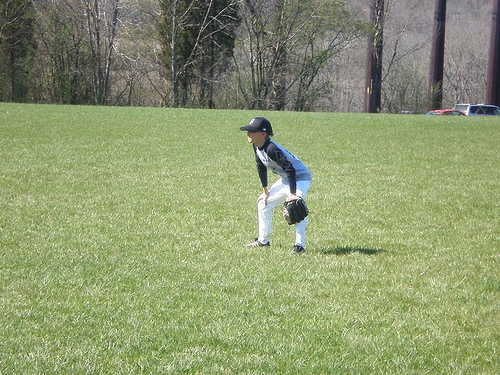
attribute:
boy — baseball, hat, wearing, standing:
[211, 118, 316, 249]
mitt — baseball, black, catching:
[278, 203, 313, 234]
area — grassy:
[143, 173, 217, 231]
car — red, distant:
[430, 112, 456, 123]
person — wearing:
[232, 93, 329, 212]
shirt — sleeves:
[248, 151, 303, 194]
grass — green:
[135, 167, 202, 273]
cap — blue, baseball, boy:
[242, 120, 266, 130]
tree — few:
[161, 25, 268, 101]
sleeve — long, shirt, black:
[251, 171, 293, 204]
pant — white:
[239, 200, 288, 243]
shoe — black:
[229, 232, 318, 276]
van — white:
[460, 105, 491, 126]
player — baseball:
[231, 93, 347, 270]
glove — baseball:
[280, 198, 304, 210]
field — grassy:
[157, 108, 212, 162]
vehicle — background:
[401, 84, 494, 155]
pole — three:
[349, 20, 414, 125]